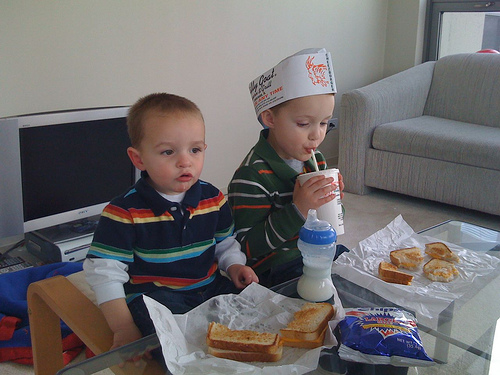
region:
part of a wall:
[168, 20, 228, 77]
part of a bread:
[239, 323, 274, 338]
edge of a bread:
[229, 335, 262, 355]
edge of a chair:
[29, 306, 64, 348]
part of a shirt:
[156, 222, 198, 265]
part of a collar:
[181, 176, 219, 228]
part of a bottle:
[303, 241, 315, 256]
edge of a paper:
[141, 303, 185, 358]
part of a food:
[347, 310, 377, 343]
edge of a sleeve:
[97, 290, 111, 311]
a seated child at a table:
[81, 89, 255, 342]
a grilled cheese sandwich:
[193, 292, 338, 364]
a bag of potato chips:
[328, 299, 443, 371]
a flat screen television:
[0, 107, 136, 235]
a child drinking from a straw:
[227, 47, 352, 276]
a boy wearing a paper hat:
[219, 42, 351, 269]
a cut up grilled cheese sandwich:
[371, 228, 461, 290]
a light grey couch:
[330, 37, 498, 223]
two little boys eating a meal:
[86, 47, 476, 368]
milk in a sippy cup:
[289, 201, 338, 308]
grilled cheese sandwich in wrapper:
[201, 300, 333, 366]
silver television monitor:
[1, 103, 148, 248]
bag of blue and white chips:
[331, 299, 444, 371]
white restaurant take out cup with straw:
[298, 146, 347, 241]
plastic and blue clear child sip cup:
[296, 205, 339, 305]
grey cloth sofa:
[337, 49, 499, 218]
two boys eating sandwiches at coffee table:
[86, 35, 471, 366]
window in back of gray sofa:
[422, 1, 498, 66]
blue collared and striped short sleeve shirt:
[87, 171, 234, 292]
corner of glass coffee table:
[58, 334, 173, 373]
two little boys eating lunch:
[123, 46, 455, 344]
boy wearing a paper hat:
[243, 42, 352, 115]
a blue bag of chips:
[336, 295, 433, 372]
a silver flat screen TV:
[3, 115, 130, 220]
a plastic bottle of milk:
[295, 211, 343, 297]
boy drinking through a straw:
[247, 56, 360, 223]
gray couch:
[363, 35, 499, 193]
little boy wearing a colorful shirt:
[121, 109, 230, 297]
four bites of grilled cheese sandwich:
[368, 206, 485, 291]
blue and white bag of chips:
[336, 303, 433, 363]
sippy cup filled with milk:
[297, 208, 335, 303]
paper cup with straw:
[300, 148, 346, 234]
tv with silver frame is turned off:
[5, 104, 145, 229]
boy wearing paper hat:
[235, 51, 352, 289]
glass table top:
[46, 216, 498, 372]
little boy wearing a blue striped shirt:
[84, 93, 266, 344]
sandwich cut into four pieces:
[380, 238, 458, 283]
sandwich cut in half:
[204, 304, 334, 359]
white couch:
[340, 49, 498, 216]